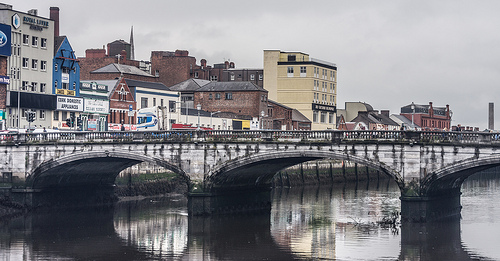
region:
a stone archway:
[201, 148, 406, 214]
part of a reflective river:
[1, 192, 497, 259]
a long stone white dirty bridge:
[1, 128, 498, 224]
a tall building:
[262, 47, 338, 134]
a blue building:
[48, 5, 83, 101]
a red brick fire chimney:
[50, 5, 60, 40]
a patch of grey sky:
[341, 5, 481, 82]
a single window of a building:
[39, 36, 47, 46]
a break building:
[191, 81, 268, 124]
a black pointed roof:
[195, 78, 268, 93]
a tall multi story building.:
[264, 37, 346, 147]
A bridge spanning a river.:
[3, 116, 495, 259]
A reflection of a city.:
[256, 190, 401, 259]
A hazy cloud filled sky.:
[18, 3, 498, 128]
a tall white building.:
[1, 9, 68, 134]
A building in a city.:
[101, 20, 140, 68]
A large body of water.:
[0, 186, 495, 259]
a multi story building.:
[257, 37, 343, 144]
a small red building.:
[137, 38, 206, 88]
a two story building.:
[393, 88, 461, 143]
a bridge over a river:
[1, 116, 493, 256]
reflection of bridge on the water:
[14, 200, 170, 259]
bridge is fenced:
[2, 123, 497, 158]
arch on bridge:
[16, 148, 196, 205]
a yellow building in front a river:
[263, 40, 347, 137]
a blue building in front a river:
[54, 31, 86, 122]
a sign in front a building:
[51, 89, 88, 114]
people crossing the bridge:
[26, 120, 207, 150]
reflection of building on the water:
[285, 183, 370, 260]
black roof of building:
[190, 75, 270, 110]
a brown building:
[265, 44, 345, 128]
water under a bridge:
[3, 147, 498, 260]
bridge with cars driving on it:
[0, 121, 464, 149]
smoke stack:
[482, 98, 497, 139]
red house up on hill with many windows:
[400, 100, 455, 136]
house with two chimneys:
[340, 100, 400, 141]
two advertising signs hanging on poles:
[40, 95, 110, 111]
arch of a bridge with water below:
[195, 160, 460, 225]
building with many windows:
[130, 80, 180, 130]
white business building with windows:
[0, 0, 60, 110]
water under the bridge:
[66, 154, 230, 251]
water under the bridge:
[302, 129, 418, 249]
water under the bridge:
[278, 181, 436, 255]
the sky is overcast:
[303, 20, 392, 75]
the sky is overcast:
[150, 14, 207, 55]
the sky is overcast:
[427, 39, 497, 132]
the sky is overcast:
[195, 22, 367, 74]